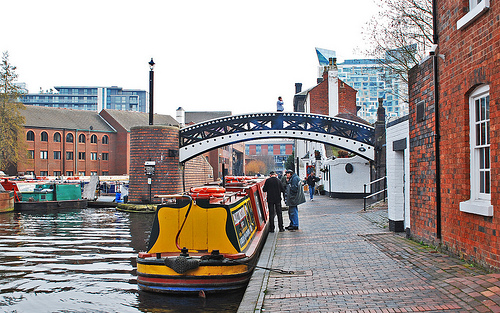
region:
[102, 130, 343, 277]
Boats along the walkway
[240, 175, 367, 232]
People in the walkway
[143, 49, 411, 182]
Walkway overpass with a person standing on it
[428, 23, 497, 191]
Brick building with a window on it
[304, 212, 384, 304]
Brick walk way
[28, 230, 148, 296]
Canal with boats docked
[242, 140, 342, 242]
People getting on the boat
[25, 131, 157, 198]
Lots of windows in the building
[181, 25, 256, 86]
The sky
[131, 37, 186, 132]
A street light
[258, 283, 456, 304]
red lines in the side walk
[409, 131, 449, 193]
red and black bricks on the wall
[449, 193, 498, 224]
large white window sill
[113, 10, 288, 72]
crystal clear skies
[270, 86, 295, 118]
person standing on the bridge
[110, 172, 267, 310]
yellow and black boat in the water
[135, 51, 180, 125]
large black post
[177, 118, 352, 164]
small black spots on bridge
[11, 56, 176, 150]
tall blue building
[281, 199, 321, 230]
man wearing blue jeans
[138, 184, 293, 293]
the boat is yellow with blue and red trim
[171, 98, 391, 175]
the bridge is blue and white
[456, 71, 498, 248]
the window is white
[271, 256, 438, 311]
the walkway is red brick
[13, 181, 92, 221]
the boat is turquoise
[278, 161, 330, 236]
the man has on blue jeans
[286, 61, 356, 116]
the chimney is white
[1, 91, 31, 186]
there is a green leafy tree in the background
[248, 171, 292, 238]
the man is dressed in all black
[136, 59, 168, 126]
the light pole is black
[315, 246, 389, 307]
the ground is wet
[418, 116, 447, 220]
the wall is made of bricks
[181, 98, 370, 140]
the person is standing on the bridge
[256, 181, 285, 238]
the man is wearing black clothing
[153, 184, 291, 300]
the boat is docked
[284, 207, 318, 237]
the jeans are blue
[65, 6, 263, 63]
the sky is cloudy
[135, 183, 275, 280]
the boat is yellow and black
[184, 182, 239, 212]
the life saver is red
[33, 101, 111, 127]
the roof is grey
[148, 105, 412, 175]
this is a bridge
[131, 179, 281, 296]
this is a boat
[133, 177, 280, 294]
this is a yellow boat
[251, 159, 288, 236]
this is a black uniform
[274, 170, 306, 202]
this is a green jacket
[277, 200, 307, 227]
these are blue jeans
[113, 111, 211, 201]
this is a brick pillar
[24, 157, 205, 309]
this is clean water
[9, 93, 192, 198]
this is a building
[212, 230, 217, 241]
this is the color yellow